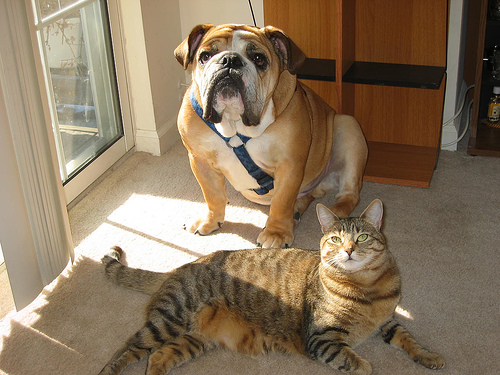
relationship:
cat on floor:
[78, 199, 452, 366] [9, 155, 500, 374]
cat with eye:
[100, 198, 452, 374] [321, 228, 342, 249]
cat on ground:
[100, 198, 452, 374] [167, 311, 430, 372]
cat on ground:
[100, 198, 452, 374] [141, 297, 477, 371]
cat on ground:
[100, 198, 452, 374] [145, 324, 426, 373]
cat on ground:
[100, 198, 452, 374] [107, 315, 494, 356]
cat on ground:
[100, 198, 452, 374] [138, 286, 463, 367]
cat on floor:
[100, 198, 452, 374] [94, 199, 499, 357]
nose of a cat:
[340, 241, 357, 257] [78, 199, 452, 366]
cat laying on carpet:
[100, 198, 452, 374] [426, 233, 463, 328]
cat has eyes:
[100, 198, 452, 374] [320, 227, 372, 244]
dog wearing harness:
[171, 22, 369, 249] [238, 158, 284, 196]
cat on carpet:
[78, 199, 452, 366] [424, 272, 454, 327]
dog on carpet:
[140, 20, 376, 231] [424, 272, 454, 327]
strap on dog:
[181, 99, 270, 201] [161, 17, 387, 250]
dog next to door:
[171, 22, 369, 249] [19, 0, 149, 184]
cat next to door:
[78, 199, 452, 366] [19, 0, 149, 184]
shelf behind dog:
[265, 51, 448, 96] [138, 5, 373, 250]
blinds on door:
[0, 3, 96, 310] [32, 1, 149, 216]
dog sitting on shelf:
[171, 22, 369, 249] [258, 1, 445, 188]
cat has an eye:
[78, 199, 452, 366] [324, 228, 344, 248]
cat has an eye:
[78, 199, 452, 366] [351, 227, 374, 244]